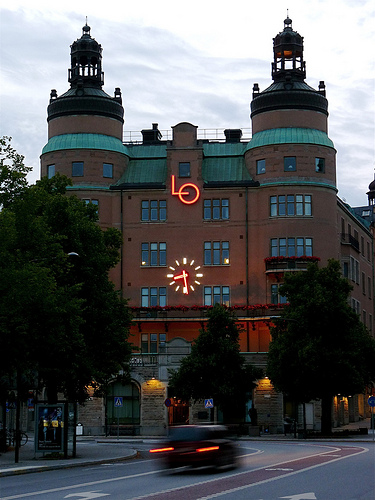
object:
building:
[38, 6, 375, 438]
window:
[202, 197, 211, 221]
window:
[221, 197, 230, 220]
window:
[256, 157, 267, 175]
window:
[283, 154, 297, 172]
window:
[314, 155, 325, 175]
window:
[179, 161, 191, 178]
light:
[196, 445, 220, 453]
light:
[149, 446, 174, 453]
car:
[149, 422, 238, 475]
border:
[34, 401, 42, 453]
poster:
[36, 404, 65, 451]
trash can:
[75, 423, 83, 436]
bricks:
[147, 399, 158, 407]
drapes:
[105, 383, 139, 425]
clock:
[166, 256, 204, 295]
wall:
[123, 192, 247, 307]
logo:
[171, 175, 201, 206]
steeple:
[67, 17, 105, 87]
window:
[140, 285, 167, 307]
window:
[203, 284, 230, 307]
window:
[270, 282, 288, 305]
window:
[270, 236, 314, 257]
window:
[203, 239, 230, 265]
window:
[141, 241, 167, 267]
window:
[150, 200, 159, 221]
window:
[138, 198, 168, 223]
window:
[270, 194, 313, 216]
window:
[140, 332, 165, 353]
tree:
[165, 301, 265, 433]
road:
[2, 428, 375, 497]